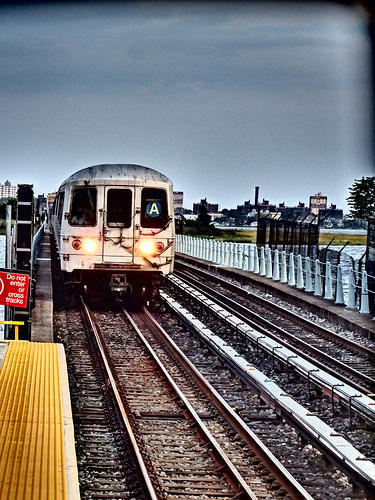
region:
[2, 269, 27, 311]
The red and white sign.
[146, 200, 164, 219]
The A sign on the train.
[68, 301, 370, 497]
The metal train tracks.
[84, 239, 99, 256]
Left front light on the train.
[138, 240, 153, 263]
Right front light on the train.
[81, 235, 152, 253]
The train lights.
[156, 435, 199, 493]
The rocks between the tracks.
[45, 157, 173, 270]
The A train on the tracks.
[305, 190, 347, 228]
Building on the right side.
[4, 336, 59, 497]
The yellow platform.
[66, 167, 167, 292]
white front of train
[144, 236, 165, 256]
light on front of train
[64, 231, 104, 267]
light on front of train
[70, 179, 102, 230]
window on front of train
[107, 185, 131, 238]
window on front of train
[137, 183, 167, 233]
window on front of train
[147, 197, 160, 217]
blue sign on train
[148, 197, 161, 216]
white letter on sign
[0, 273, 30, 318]
red sign on train stop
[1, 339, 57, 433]
yellow waiting platform for train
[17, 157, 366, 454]
train sitting on tracks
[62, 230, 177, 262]
rear lights on train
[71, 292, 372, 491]
cinder between tracks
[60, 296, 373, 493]
tracks are made of steel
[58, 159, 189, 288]
train is white and dirty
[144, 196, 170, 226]
letter A on rear window of train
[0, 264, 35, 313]
sign says Do not enter or cross tracks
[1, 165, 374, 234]
cityscape in distance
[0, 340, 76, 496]
ribbed yellow loading platform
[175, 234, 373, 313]
white fence along train tracks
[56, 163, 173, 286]
white front of train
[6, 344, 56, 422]
yellow train platform by tracks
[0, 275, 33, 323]
red sign by tracks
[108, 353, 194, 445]
metal train tracks on ground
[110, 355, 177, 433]
rocks in between train tracks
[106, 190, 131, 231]
window on front of train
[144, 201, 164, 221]
blue sign on train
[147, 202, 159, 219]
white letter on front of train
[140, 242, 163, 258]
orange light on train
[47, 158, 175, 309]
Train driving on train tracks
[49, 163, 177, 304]
White train on tracks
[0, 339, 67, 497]
Yellow grate next to train tracks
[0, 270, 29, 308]
Red sign with white writing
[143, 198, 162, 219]
Blue circle with a white A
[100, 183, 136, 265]
White door of a train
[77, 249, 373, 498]
Metal train tracks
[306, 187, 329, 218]
Tall brown brick building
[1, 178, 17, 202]
Tall white office building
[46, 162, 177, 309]
White train on train tracks